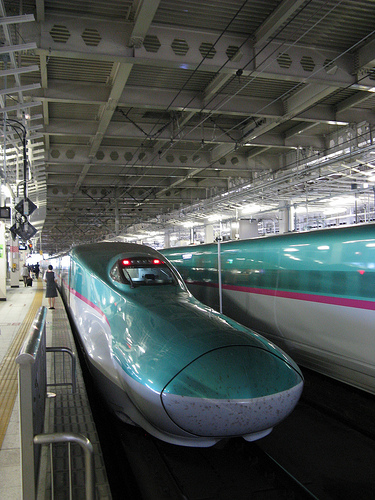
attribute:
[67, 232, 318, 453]
train — white, green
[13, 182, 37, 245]
train signs — back side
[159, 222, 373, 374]
train — green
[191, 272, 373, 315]
stripe — red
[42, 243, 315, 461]
train — green, white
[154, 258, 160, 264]
light — red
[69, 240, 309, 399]
train top — aqua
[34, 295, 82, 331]
shoes — black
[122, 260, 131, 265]
light — red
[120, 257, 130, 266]
light — red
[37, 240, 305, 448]
train — large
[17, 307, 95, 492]
safety railing — metal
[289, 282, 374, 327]
stripe — purple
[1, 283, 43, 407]
bumps — yellow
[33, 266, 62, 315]
woman dress — black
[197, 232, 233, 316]
stripe — yellow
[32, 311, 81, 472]
railing — silver 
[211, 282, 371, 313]
stripe — purple